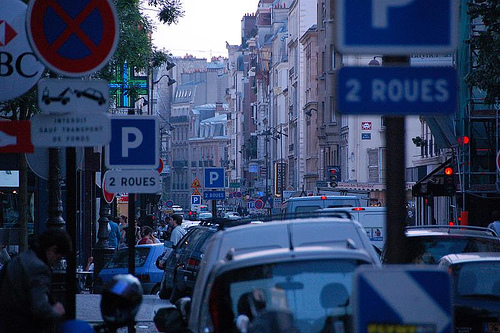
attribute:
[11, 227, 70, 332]
man — walking, looking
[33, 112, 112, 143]
sign — white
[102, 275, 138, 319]
helmet — silver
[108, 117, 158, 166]
sign — blue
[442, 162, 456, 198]
traffic light — red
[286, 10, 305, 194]
building — tall, white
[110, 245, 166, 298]
car — parked, blue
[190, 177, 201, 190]
sign — yellow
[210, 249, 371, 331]
mirror — rearview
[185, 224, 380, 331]
van — white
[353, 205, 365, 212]
brake light — lit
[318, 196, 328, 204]
brake light — lit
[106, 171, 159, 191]
sign — black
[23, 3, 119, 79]
sign — red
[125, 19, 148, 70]
leaves — green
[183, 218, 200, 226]
car — white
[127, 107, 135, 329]
pole — black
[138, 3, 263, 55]
sky — gray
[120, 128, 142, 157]
writing — white, bold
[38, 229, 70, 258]
hair — black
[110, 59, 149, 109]
cross — lit up